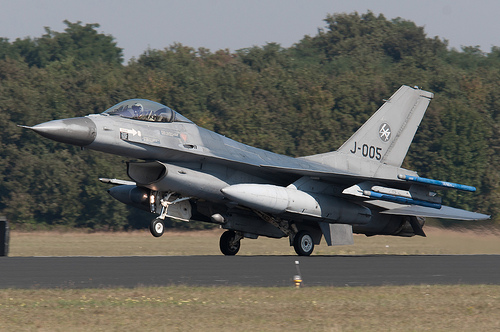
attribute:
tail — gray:
[337, 83, 433, 167]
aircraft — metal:
[21, 85, 472, 262]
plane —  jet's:
[31, 79, 473, 280]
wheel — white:
[273, 222, 325, 262]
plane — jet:
[33, 35, 499, 285]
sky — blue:
[2, 0, 498, 56]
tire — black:
[294, 228, 320, 259]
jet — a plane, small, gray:
[14, 81, 491, 255]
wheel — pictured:
[293, 227, 322, 255]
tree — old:
[326, 97, 342, 138]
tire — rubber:
[291, 232, 320, 257]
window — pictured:
[97, 92, 186, 125]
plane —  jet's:
[7, 69, 499, 284]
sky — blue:
[444, 10, 487, 40]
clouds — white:
[131, 5, 250, 35]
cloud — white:
[3, 2, 495, 62]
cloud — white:
[0, 0, 498, 67]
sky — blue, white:
[3, 0, 499, 64]